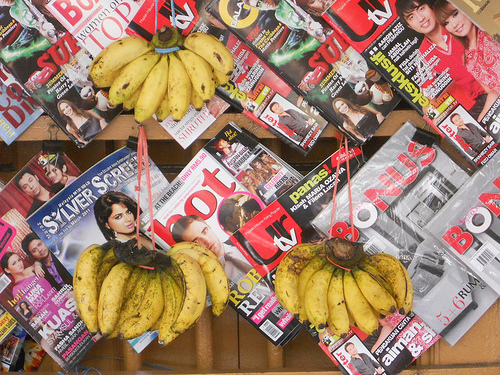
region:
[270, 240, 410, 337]
A bunch of bananas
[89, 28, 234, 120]
A bunch of bananas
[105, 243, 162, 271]
Black tops of bananas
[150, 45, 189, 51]
Blue tie around bananas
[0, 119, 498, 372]
Magazines underneath some bananas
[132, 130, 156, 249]
Red string around bananas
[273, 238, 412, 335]
ripe bunch of bananas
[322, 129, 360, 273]
Red string holding bananas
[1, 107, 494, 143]
Wooden board with pegs for display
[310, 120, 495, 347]
Plastic wrapped magazine on display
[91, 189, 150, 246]
Model on magazine cover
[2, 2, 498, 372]
Newstand with magazines and bananas for sale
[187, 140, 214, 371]
Wooden dowel on newstand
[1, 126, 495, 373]
Magazines on display at newstand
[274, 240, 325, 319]
Ripe banana with brown spots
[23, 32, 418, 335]
three bunches of bananas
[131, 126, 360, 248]
red strings attached to bananas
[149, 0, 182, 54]
blue string attached to bananas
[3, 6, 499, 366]
two rows of magazines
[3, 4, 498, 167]
top row of magazines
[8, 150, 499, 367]
bottom row of magazines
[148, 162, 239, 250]
red lettering on white background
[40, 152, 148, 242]
white lettering on blue background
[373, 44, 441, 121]
yellow lettering on black background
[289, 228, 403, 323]
brown spots on yellow bananas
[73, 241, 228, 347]
bananas are spotted and yellow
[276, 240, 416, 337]
bananas are ripe and yellow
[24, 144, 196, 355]
magizine is blue and white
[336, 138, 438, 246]
words on mag say bonus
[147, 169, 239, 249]
word on mag says bot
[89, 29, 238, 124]
bananas are hanging by as string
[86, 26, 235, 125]
bananas are yellow and ripe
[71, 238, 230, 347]
bananas are yellow and ripe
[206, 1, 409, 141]
magizine is black and yellow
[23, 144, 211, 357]
magazine is titled silver screen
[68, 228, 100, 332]
rot on yellow banana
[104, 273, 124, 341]
rot on yellow banana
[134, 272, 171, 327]
rot on yellow banana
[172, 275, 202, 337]
rot on yellow banana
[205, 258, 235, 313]
rot on yellow banana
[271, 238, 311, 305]
rot on yellow banana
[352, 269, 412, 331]
rot on yellow banana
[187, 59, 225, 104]
rot on yellow banana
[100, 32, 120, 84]
rot on yellow banana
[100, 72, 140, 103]
rot on yellow banana